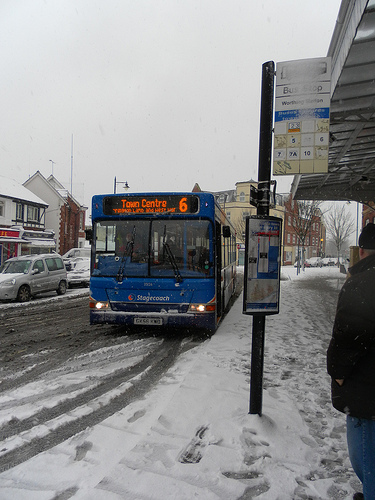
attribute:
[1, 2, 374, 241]
sky — light grey, gray, dreary, overcast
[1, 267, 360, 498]
snow — white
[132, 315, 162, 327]
license plate — white, black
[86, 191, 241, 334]
bus — blue, public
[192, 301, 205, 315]
headlights — on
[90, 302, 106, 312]
headlights — on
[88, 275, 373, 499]
sidewalk — snowy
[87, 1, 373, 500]
stop — bus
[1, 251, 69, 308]
vehicles — parked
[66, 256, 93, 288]
vehicles — parked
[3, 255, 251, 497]
road — snow covered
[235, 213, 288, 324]
sign — informational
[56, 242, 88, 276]
suv — small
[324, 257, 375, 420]
jacket — black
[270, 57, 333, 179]
sign — hanging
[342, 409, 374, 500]
pants — blue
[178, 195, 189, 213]
number — 6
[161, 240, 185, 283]
wipers — black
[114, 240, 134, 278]
wipers — black